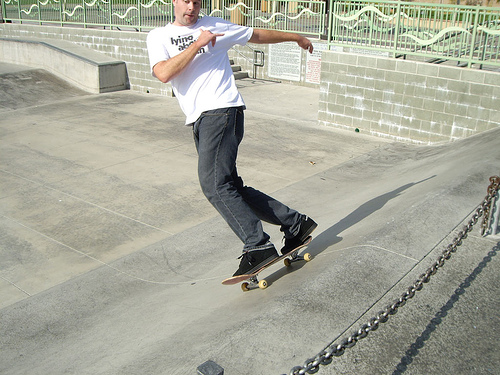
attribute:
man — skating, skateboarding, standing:
[128, 0, 339, 274]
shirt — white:
[138, 15, 258, 131]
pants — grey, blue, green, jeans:
[183, 100, 303, 258]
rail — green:
[329, 1, 500, 79]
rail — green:
[1, 0, 326, 47]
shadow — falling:
[234, 168, 442, 298]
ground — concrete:
[1, 126, 499, 375]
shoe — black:
[224, 232, 282, 287]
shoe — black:
[276, 211, 322, 256]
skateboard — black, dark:
[212, 231, 320, 297]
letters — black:
[165, 30, 212, 65]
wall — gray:
[315, 40, 500, 161]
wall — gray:
[0, 19, 185, 106]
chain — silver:
[203, 169, 498, 374]